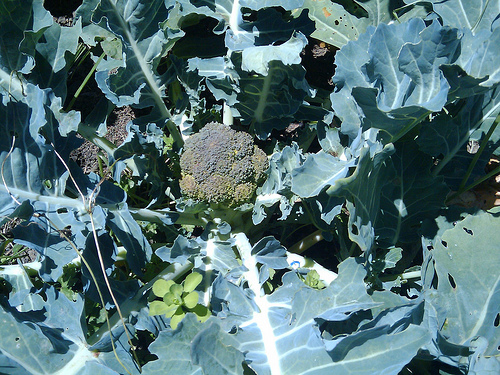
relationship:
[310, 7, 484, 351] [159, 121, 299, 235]
leaves around broccoli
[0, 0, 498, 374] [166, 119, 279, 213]
leaves around broccoli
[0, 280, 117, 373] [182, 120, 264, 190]
leaves around broccoli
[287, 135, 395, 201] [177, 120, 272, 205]
leaf on broccoli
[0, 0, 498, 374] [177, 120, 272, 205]
leaves on broccoli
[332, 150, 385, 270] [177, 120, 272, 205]
leaves around broccoli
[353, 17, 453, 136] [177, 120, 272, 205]
leaves around broccoli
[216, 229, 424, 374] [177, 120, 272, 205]
leaves around broccoli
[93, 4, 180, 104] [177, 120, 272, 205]
leaves around broccoli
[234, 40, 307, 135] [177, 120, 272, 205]
leaves around broccoli